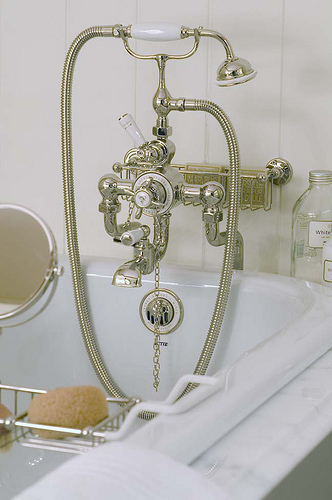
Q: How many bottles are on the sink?
A: Two.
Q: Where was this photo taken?
A: The upstairs bathroom.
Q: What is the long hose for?
A: The shower.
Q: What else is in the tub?
A: A mirror.